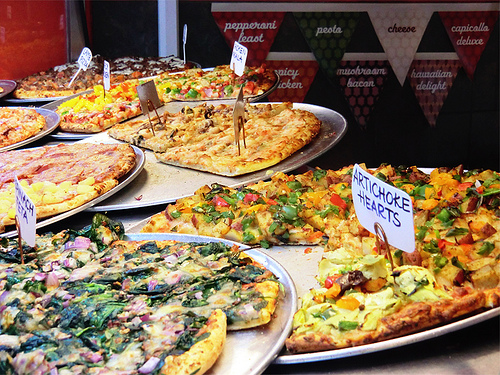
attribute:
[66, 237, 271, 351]
spinach — green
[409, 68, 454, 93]
words — hawaiian delight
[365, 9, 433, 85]
flag — white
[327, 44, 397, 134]
banner — bottom middle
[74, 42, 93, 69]
sign — small, white, paper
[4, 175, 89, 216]
toppings — yellow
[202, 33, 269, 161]
sign — white, small, paper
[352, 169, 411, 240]
letters — dark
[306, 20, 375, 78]
banner — green, pasta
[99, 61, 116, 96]
sign — paper, small, white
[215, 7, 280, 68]
flag — red, plast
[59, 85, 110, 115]
pineapple — yellow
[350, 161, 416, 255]
sign — small, white, paper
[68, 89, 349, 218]
tray — silver, round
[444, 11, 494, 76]
flag — red colored, plastic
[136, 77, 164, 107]
sign — paper, small, white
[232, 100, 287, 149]
sign — small, white, paper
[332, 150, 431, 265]
banner — red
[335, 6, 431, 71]
banner — white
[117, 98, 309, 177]
slices — metal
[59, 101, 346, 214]
tray — large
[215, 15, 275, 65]
banner — pepperoni feast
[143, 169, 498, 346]
pizza — round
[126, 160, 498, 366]
tray — large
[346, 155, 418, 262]
sign — small, white, paper